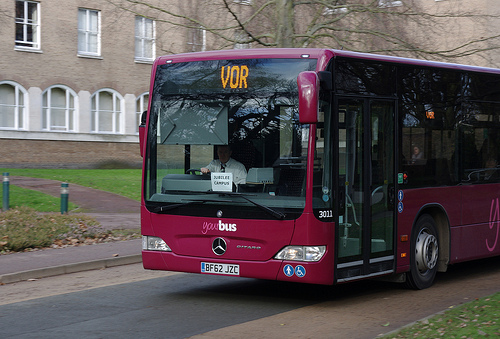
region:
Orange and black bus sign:
[215, 63, 252, 94]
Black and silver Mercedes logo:
[205, 233, 232, 258]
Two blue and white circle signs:
[282, 264, 309, 278]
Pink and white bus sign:
[197, 218, 239, 233]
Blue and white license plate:
[196, 260, 242, 274]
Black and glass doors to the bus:
[334, 100, 400, 262]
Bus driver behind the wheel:
[190, 139, 252, 189]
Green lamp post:
[56, 179, 74, 214]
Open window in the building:
[14, 0, 41, 54]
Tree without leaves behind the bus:
[106, 0, 498, 59]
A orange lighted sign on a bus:
[201, 57, 266, 92]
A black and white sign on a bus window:
[203, 169, 243, 207]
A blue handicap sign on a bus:
[290, 263, 311, 283]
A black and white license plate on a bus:
[194, 256, 252, 281]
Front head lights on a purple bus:
[127, 231, 338, 267]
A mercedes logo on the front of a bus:
[203, 231, 234, 263]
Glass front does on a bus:
[332, 90, 401, 286]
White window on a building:
[34, 75, 82, 147]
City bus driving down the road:
[122, 44, 499, 295]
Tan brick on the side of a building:
[53, 54, 75, 72]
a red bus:
[140, 45, 497, 290]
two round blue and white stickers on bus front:
[280, 260, 305, 275]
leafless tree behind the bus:
[102, 0, 497, 60]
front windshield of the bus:
[147, 95, 302, 191]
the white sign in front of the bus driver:
[210, 170, 232, 187]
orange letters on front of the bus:
[220, 62, 250, 87]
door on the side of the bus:
[330, 95, 390, 277]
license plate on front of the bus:
[200, 260, 240, 275]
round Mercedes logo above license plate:
[210, 235, 226, 255]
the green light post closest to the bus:
[56, 180, 71, 215]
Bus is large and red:
[153, 50, 498, 282]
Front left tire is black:
[403, 220, 453, 282]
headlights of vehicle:
[140, 233, 336, 270]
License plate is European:
[193, 254, 248, 280]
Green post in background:
[56, 175, 75, 215]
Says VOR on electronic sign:
[209, 55, 265, 102]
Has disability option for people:
[279, 263, 311, 280]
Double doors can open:
[333, 106, 400, 268]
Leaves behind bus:
[7, 210, 93, 245]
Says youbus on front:
[192, 215, 249, 237]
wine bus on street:
[139, 48, 499, 283]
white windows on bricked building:
[3, 5, 244, 140]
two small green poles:
[1, 171, 70, 216]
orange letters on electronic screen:
[216, 60, 251, 92]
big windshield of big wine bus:
[148, 58, 308, 225]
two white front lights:
[138, 233, 334, 263]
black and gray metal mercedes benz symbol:
[209, 235, 229, 259]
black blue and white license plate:
[198, 260, 239, 278]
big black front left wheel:
[401, 210, 446, 287]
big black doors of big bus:
[330, 94, 398, 281]